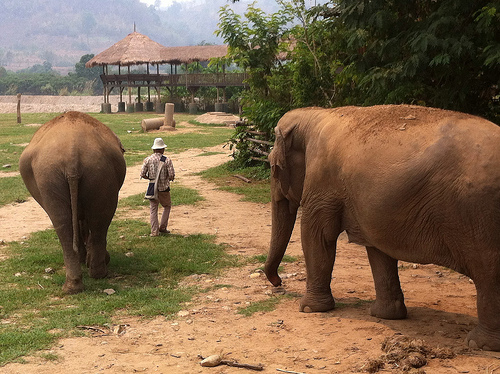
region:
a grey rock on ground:
[192, 350, 229, 370]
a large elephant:
[259, 113, 499, 343]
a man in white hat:
[142, 123, 186, 248]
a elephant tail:
[58, 163, 88, 254]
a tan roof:
[87, 36, 169, 67]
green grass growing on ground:
[10, 290, 68, 345]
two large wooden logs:
[133, 97, 184, 134]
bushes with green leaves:
[7, 63, 97, 95]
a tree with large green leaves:
[342, 11, 498, 96]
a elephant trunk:
[260, 185, 299, 290]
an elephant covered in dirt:
[229, 94, 498, 354]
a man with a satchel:
[135, 134, 188, 241]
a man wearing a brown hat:
[137, 129, 184, 244]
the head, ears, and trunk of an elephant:
[238, 94, 325, 304]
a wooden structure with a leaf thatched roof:
[73, 12, 345, 119]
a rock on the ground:
[193, 344, 231, 369]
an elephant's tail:
[57, 153, 97, 265]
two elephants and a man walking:
[8, 94, 499, 355]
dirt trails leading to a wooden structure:
[0, 113, 498, 372]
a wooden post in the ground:
[11, 86, 27, 129]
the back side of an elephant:
[20, 107, 133, 289]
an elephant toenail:
[302, 303, 313, 315]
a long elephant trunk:
[260, 181, 296, 295]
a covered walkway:
[96, 29, 257, 111]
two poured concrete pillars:
[140, 100, 191, 139]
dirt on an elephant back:
[336, 100, 452, 143]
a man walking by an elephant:
[133, 138, 202, 243]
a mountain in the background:
[1, 4, 205, 78]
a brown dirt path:
[0, 128, 254, 256]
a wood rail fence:
[233, 117, 281, 170]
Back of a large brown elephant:
[18, 123, 126, 285]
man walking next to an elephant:
[139, 136, 175, 235]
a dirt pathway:
[186, 168, 265, 249]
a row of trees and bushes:
[3, 54, 102, 91]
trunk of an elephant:
[263, 181, 298, 292]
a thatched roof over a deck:
[81, 48, 217, 63]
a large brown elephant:
[258, 100, 490, 353]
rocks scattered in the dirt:
[171, 287, 226, 329]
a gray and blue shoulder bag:
[146, 153, 169, 201]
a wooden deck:
[98, 64, 245, 85]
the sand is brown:
[200, 192, 262, 234]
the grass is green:
[121, 245, 183, 310]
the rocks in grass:
[8, 260, 58, 307]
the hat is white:
[150, 132, 172, 149]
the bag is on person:
[137, 131, 179, 245]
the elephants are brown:
[25, 114, 499, 329]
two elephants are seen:
[35, 96, 485, 319]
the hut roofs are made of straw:
[108, 30, 238, 72]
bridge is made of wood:
[100, 75, 249, 97]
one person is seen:
[143, 135, 170, 237]